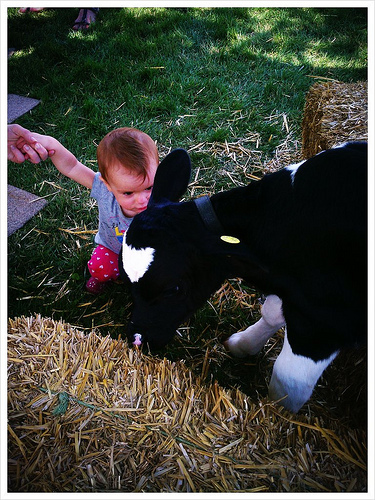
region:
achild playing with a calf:
[67, 138, 216, 338]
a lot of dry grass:
[11, 399, 343, 494]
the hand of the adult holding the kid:
[7, 126, 149, 215]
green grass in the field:
[119, 22, 289, 123]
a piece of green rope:
[40, 383, 128, 426]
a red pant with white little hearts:
[86, 244, 119, 291]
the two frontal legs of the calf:
[232, 290, 328, 406]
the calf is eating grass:
[120, 228, 253, 364]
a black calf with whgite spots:
[135, 169, 368, 401]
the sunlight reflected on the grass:
[241, 11, 351, 71]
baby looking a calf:
[23, 111, 371, 426]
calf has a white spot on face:
[109, 207, 199, 344]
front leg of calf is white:
[265, 347, 326, 422]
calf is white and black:
[125, 145, 373, 428]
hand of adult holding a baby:
[4, 110, 166, 306]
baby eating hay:
[10, 141, 373, 490]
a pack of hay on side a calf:
[11, 296, 359, 497]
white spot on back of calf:
[266, 130, 356, 188]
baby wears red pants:
[25, 119, 176, 305]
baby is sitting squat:
[15, 118, 195, 319]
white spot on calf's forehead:
[122, 230, 155, 282]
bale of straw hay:
[9, 315, 373, 491]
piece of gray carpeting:
[6, 184, 51, 236]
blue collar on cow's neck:
[193, 195, 225, 233]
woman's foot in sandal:
[70, 7, 97, 32]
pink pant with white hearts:
[87, 245, 118, 282]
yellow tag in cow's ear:
[218, 235, 243, 244]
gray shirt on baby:
[90, 170, 142, 253]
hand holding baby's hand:
[8, 125, 54, 165]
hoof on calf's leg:
[222, 333, 240, 359]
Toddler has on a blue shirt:
[88, 170, 134, 255]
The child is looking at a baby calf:
[15, 127, 176, 295]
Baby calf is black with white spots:
[117, 137, 372, 491]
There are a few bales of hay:
[7, 71, 371, 493]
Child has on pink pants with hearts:
[85, 243, 118, 281]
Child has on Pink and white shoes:
[84, 278, 102, 293]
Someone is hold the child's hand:
[8, 122, 54, 164]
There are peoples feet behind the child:
[16, 8, 108, 35]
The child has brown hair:
[96, 125, 158, 188]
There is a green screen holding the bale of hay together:
[29, 381, 324, 494]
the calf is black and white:
[132, 192, 344, 374]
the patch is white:
[112, 237, 152, 266]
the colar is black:
[190, 197, 236, 256]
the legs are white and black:
[270, 339, 328, 400]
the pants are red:
[85, 250, 119, 290]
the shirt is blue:
[93, 200, 121, 247]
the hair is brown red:
[103, 119, 151, 178]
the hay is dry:
[81, 352, 223, 451]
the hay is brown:
[67, 361, 210, 460]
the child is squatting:
[79, 150, 159, 277]